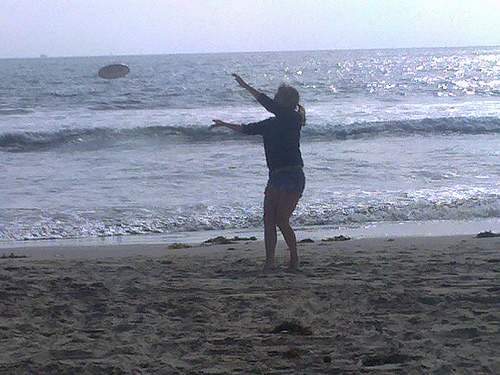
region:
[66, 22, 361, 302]
A lady on the beach preparing to catch a frisbee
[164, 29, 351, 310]
A lady on the beach with her arms stretched out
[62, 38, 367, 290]
A woman preparing to catch a frisbee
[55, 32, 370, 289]
A young lady waiting to catch up Frisbie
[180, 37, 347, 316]
Lady with a ponytail on the beach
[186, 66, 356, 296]
A lady wearing blue jean shorts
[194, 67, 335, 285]
A woman on the beach wearing shorts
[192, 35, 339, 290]
this is a person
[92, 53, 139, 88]
this is a Frisbee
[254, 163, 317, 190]
the lady is in shorts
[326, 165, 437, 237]
this is a wave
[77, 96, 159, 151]
this is a wave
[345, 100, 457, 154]
this is a wave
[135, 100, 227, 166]
this is a wave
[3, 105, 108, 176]
this is a wave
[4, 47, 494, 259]
ocean with a row of short waves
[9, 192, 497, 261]
moving water on edge of beach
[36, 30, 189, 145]
white frisbee traveling through air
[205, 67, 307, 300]
woman on beach standing on sand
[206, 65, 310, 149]
arms extended fully in front of woman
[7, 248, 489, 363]
rough texture of moist sand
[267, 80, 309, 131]
woman with hair pulled back into ponytail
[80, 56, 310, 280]
woman ready to catch frisbee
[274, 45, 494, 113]
ocean surface glistening with sun's reflection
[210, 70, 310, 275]
woman wearing short shorts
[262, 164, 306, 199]
short shorts are blue jean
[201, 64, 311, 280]
woman standing on a sandy beach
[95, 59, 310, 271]
woman catching a frisbee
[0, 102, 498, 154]
single ocean wave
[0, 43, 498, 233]
vast ocean with a single wave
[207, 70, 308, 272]
woman wearing her hair in a ponytail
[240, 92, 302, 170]
dark long sleeve shirt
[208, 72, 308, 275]
woman wearing a shirt and shorts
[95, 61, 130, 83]
frisbee in mid air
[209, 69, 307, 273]
a woman is standing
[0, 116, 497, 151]
the wave is small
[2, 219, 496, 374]
sand on the beach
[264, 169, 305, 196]
woman is wearing shorts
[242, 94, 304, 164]
the shirt is blue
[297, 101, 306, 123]
woman has a ponytail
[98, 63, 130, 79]
frisbee in the air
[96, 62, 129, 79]
the frisbee is white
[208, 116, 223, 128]
hand of a woman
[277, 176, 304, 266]
leg of a woman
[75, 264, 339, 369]
the beach is sandy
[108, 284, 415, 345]
the sand is lumpy